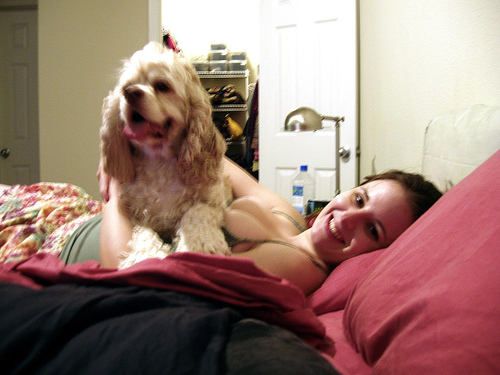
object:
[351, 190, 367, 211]
alarm eyes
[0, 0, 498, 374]
room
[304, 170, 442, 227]
hair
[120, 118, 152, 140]
tongue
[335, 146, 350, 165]
knob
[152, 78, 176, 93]
dog eye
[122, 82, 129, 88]
dog eye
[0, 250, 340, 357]
sheets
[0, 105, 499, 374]
bed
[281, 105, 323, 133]
lamp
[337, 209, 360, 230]
nose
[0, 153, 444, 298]
girl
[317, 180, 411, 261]
face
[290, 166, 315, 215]
plastic bottle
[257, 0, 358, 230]
door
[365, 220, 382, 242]
eye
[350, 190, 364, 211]
eye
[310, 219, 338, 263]
chin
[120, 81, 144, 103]
nose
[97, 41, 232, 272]
dog